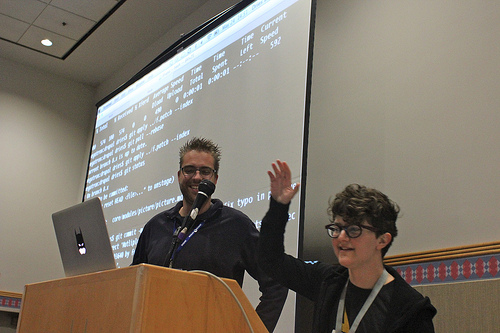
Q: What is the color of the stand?
A: Brown.